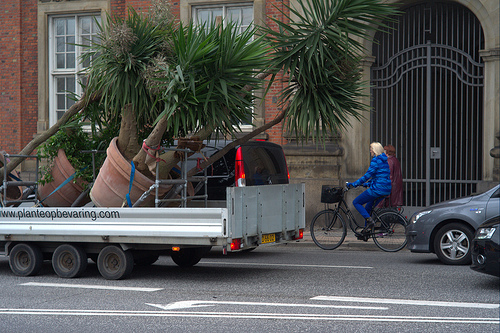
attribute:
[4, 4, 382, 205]
plants — potted, big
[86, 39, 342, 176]
plant — green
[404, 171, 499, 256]
car — grey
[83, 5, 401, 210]
plant — green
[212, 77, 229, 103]
stem — green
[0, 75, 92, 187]
stem — green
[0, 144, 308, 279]
truck — flatbed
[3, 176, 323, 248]
flatbed — potted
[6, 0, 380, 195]
trees — large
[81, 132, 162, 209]
flowerpot — large, brown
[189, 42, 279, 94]
plant — green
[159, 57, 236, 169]
plant — green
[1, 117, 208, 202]
pots — big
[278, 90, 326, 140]
plant — green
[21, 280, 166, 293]
line — white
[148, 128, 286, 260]
suv — black